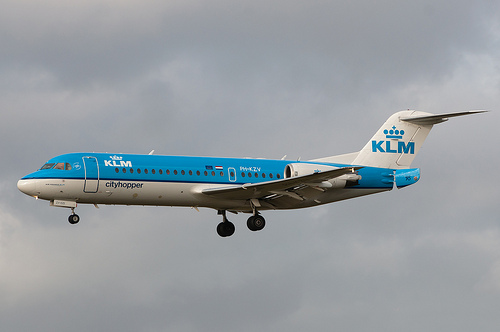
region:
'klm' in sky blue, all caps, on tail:
[369, 131, 421, 161]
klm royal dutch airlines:
[88, 120, 424, 213]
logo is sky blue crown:
[375, 118, 410, 139]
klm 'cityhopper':
[103, 178, 144, 189]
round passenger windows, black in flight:
[106, 160, 301, 178]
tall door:
[76, 153, 101, 194]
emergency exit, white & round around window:
[221, 163, 237, 185]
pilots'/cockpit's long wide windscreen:
[30, 157, 77, 167]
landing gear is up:
[60, 205, 80, 225]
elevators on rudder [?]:
[353, 109, 487, 166]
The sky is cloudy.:
[7, 5, 489, 326]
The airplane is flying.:
[23, 114, 487, 237]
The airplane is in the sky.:
[30, 102, 482, 244]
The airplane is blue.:
[10, 81, 492, 233]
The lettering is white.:
[93, 150, 138, 171]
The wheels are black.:
[61, 205, 278, 239]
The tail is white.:
[340, 88, 482, 164]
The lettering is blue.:
[365, 124, 425, 152]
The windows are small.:
[106, 164, 284, 179]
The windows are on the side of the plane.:
[108, 160, 287, 180]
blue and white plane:
[74, 124, 374, 231]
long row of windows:
[87, 160, 312, 205]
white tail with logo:
[363, 101, 418, 209]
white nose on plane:
[4, 165, 52, 213]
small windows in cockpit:
[44, 161, 74, 180]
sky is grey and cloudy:
[72, 45, 292, 140]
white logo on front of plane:
[110, 152, 140, 170]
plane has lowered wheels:
[57, 213, 299, 242]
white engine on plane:
[281, 154, 350, 186]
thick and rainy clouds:
[124, 29, 274, 113]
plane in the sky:
[12, 83, 499, 251]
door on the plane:
[80, 156, 99, 197]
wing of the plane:
[241, 166, 361, 186]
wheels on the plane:
[212, 212, 272, 238]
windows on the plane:
[107, 166, 225, 178]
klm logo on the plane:
[372, 125, 420, 160]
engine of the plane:
[285, 160, 317, 177]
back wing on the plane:
[411, 102, 485, 123]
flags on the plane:
[202, 160, 224, 171]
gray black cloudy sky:
[117, 56, 235, 102]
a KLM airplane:
[17, 110, 496, 233]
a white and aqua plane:
[14, 110, 486, 239]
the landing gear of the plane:
[66, 213, 266, 237]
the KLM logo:
[370, 125, 415, 155]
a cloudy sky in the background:
[3, 38, 467, 88]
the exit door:
[82, 155, 99, 195]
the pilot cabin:
[41, 161, 70, 170]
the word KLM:
[369, 138, 414, 154]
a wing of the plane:
[196, 167, 356, 197]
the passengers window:
[151, 168, 219, 177]